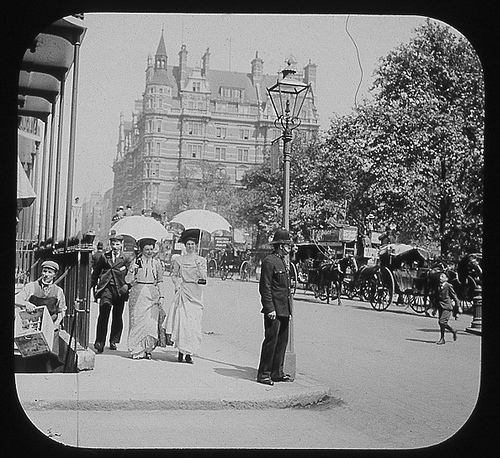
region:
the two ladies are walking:
[133, 219, 228, 289]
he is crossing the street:
[424, 265, 457, 345]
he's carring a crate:
[20, 253, 67, 365]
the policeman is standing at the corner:
[262, 222, 307, 317]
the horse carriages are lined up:
[301, 233, 479, 298]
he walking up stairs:
[26, 263, 78, 380]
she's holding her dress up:
[173, 253, 217, 328]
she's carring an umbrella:
[116, 212, 159, 282]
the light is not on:
[263, 54, 312, 147]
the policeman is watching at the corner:
[261, 220, 310, 319]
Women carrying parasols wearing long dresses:
[126, 205, 235, 359]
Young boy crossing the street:
[428, 260, 473, 346]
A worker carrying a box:
[17, 253, 77, 373]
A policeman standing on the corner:
[255, 226, 304, 389]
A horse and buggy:
[365, 240, 480, 319]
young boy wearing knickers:
[436, 271, 461, 353]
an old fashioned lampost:
[258, 62, 319, 229]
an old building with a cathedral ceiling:
[120, 18, 316, 158]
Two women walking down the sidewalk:
[114, 205, 228, 361]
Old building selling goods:
[290, 232, 389, 257]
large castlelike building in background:
[116, 50, 326, 164]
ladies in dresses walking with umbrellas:
[112, 207, 213, 369]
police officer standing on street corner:
[253, 220, 293, 390]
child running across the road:
[429, 265, 463, 347]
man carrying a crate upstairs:
[16, 255, 73, 363]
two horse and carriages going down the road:
[293, 229, 435, 329]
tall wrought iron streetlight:
[270, 56, 308, 388]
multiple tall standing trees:
[303, 27, 484, 245]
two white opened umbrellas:
[105, 206, 235, 238]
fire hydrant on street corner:
[465, 277, 487, 338]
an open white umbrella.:
[167, 206, 232, 244]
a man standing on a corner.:
[243, 222, 303, 382]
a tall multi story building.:
[99, 28, 323, 211]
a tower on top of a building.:
[149, 25, 171, 74]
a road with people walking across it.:
[89, 270, 479, 397]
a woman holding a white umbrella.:
[156, 191, 247, 376]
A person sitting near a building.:
[16, 242, 75, 366]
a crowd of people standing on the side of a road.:
[174, 206, 471, 313]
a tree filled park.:
[171, 16, 486, 319]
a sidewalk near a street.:
[17, 265, 334, 402]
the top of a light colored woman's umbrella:
[170, 208, 232, 232]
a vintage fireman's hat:
[269, 228, 295, 246]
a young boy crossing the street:
[432, 271, 462, 343]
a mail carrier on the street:
[92, 235, 124, 350]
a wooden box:
[17, 305, 54, 355]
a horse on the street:
[315, 253, 356, 305]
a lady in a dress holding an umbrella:
[169, 212, 207, 363]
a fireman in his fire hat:
[258, 229, 292, 384]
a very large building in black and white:
[140, 29, 317, 210]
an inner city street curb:
[54, 391, 334, 408]